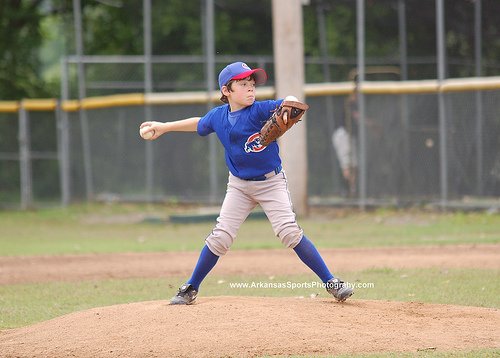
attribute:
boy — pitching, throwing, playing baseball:
[138, 60, 353, 309]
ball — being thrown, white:
[138, 125, 154, 139]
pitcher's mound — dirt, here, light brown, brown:
[1, 295, 499, 352]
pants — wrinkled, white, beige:
[206, 170, 303, 259]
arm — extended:
[141, 112, 213, 140]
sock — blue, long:
[292, 236, 332, 284]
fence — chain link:
[0, 2, 499, 209]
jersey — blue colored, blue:
[199, 99, 282, 178]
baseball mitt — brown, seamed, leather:
[258, 99, 310, 144]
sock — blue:
[188, 244, 219, 292]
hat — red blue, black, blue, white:
[216, 62, 267, 88]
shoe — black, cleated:
[167, 282, 197, 305]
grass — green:
[0, 270, 500, 329]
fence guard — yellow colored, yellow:
[1, 74, 499, 113]